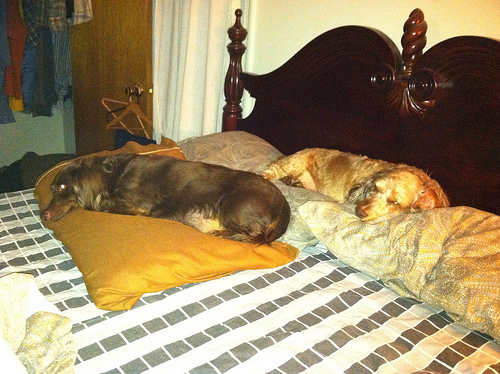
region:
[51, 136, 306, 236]
this is a dog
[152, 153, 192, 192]
the dog is black in color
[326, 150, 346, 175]
the dog is brown in color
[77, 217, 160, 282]
this is a pillow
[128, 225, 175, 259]
the pillow is yellow in color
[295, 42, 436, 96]
this is the bed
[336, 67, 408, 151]
the bed is wooden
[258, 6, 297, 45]
this is a wall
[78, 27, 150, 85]
this is the door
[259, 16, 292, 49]
the door is white in color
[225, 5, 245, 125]
dark brown polished wooden bed post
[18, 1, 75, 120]
scarfs and other clothing hanging on hook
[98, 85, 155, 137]
wooden and plastic hangers on door knob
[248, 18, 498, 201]
very deep auburn colored wooden headboard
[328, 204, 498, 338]
pillow in paisley pillow case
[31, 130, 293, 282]
dog sleeping on orange-yellow pillow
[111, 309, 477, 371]
white and black striped bed spread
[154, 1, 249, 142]
white fabric curtains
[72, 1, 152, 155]
closed wood bedroom door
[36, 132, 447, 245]
two dogs sleeping on a bed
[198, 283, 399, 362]
the comforter is black and white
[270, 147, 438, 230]
the dog is brown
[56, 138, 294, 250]
the dog is dark brown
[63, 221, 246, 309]
the pillow is orange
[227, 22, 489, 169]
the headboard is wooden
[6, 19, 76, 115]
clothes are in the closet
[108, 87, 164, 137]
hangers are on the knob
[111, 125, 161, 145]
clothes are on the hanger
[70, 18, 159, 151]
the door is brown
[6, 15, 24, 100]
the clothe is red